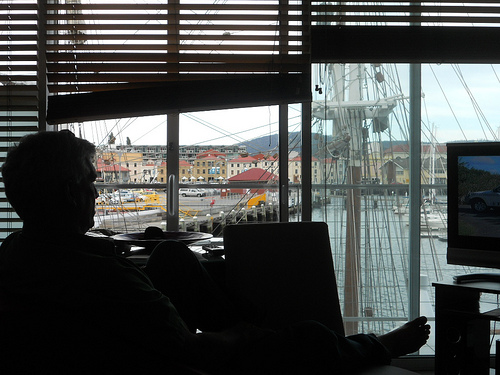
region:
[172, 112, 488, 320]
This is a harbor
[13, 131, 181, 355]
This is a man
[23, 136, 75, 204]
The hair is short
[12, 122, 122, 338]
The man is dark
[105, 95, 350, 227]
These are many buildings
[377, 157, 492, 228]
This is a screen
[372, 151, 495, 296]
This is a monitor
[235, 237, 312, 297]
This is a chair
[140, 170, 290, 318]
The chair is black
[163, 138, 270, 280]
This is a dock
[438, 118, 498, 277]
Small tv screen that is on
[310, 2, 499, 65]
Dark colored window blinds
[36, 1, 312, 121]
Dark colored window blinds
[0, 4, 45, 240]
Dark colored window blinds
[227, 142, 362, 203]
Large building out side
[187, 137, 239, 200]
Large building out side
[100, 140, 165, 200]
Large building out side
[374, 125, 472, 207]
Large building out side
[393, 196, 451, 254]
Boats in the water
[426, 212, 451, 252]
Boats in the water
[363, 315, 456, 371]
Man not wearing no shoes.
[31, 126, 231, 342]
Man staring out the window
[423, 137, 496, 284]
The television is on.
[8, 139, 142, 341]
The man is watching television.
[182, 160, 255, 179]
Windows on the building.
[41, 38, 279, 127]
Blinds on the window are open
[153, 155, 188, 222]
latch on the window.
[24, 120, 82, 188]
The man has gray hair.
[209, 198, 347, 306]
A chair in front of the person.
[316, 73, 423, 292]
Sails from a boat outside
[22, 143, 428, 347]
man relaxing in chair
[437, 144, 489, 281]
tv screen turning on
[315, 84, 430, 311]
sail boat outside window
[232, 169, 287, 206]
red top on building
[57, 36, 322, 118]
dark blinds on window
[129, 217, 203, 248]
round bowl on table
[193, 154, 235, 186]
tan building outside window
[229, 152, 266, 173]
white building outside window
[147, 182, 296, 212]
white truck outside window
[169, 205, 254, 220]
concrete bridge outside window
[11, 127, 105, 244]
man looking out window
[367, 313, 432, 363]
no shoes on right foot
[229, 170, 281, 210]
building with red top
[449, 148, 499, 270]
moniter to the right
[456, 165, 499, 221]
automobile in the screen moniter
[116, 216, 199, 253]
plate on the table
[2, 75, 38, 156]
blinds on the window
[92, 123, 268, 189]
lines crossed out the window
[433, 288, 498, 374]
stand that holds the moniter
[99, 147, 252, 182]
buildings in the distance